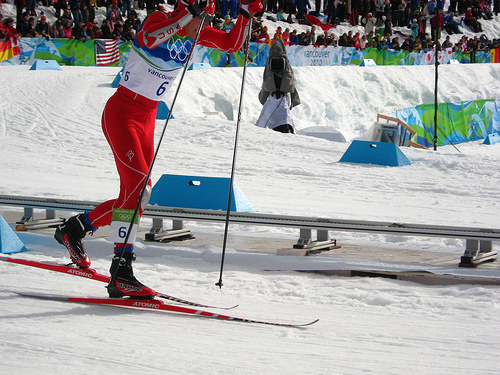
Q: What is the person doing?
A: Skiing.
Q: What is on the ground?
A: Snow.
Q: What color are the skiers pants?
A: Red.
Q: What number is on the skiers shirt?
A: Six.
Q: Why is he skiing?
A: The Olympics.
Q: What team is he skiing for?
A: USA.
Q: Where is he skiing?
A: Ski slopes.